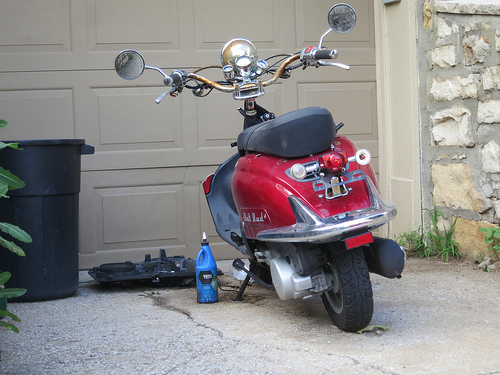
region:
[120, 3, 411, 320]
a red and black motorcycle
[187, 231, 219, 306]
a bright blue bottle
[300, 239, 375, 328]
a rear motorcycle tire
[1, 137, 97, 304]
a black trash can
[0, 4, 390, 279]
a brown garage door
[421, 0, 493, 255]
a stone built wall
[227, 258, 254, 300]
a motorcycle kickstand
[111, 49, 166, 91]
a motorcycle left rear view mirror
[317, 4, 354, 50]
a motorcycle right rearview mirror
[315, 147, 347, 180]
a motorcycle red taillight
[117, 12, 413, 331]
the red bike being worked on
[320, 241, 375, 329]
the black wheel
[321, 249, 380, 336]
the back black wheel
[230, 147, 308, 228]
the red body of the frame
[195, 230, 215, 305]
the blue bottle on the ground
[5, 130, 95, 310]
the tall black garbage can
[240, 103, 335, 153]
the black seat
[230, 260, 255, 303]
the black kick stand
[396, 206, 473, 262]
the patch of green grass on the wall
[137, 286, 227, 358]
the crack in the concrete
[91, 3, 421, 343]
This is a motorbike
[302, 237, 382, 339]
This is a wheel of a motorbike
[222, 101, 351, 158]
This is a seat of a motorbike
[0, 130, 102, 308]
This is a dustbin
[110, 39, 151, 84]
This is a left side mirror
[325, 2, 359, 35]
This is a left side mirror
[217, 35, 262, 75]
This is a head lamb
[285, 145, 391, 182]
These are break lights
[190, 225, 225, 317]
This is a bottle of water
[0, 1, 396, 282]
This is a gate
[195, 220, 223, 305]
blue bottle sitting on floor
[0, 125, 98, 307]
garbage can sitting on ground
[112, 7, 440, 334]
red scooter sitting on ground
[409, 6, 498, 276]
wall is bricks and concrete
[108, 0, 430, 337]
scooter is parked by door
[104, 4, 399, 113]
scooter with two rear view mirrors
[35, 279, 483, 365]
ground made of gray concrete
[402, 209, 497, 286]
weed growing on ground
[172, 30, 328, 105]
rust traces on scooter handle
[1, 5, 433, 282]
light gray garage door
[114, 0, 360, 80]
Rear view mirrors on moped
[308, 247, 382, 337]
Back tire of moped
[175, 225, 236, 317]
Some kind of lubricant in blue bottle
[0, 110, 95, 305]
Dark colored plastic garbage can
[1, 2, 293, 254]
Tan garage door with rectangle pattern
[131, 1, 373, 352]
Red moped parked by garage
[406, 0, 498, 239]
Stone wall with white and tan stones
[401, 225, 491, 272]
Weeds growing by stone wall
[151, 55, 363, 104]
Handle bar area of moped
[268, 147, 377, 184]
Rear light area of moped